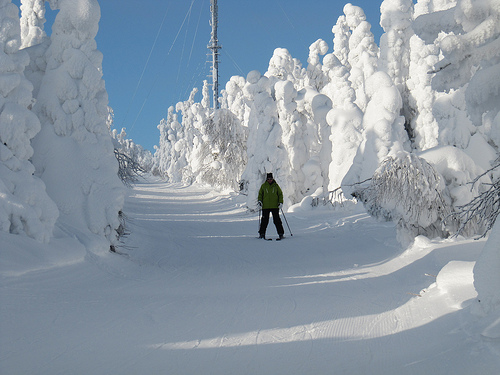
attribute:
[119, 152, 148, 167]
branch — dead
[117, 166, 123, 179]
branch — dead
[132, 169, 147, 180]
branch — dead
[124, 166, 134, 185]
branch — dead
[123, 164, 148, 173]
branch — dead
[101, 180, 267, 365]
slope — smooth, white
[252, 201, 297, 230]
poles — black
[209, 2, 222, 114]
pole — tall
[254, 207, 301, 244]
pants — black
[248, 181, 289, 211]
coat — green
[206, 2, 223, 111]
pole — power line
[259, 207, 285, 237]
pants — black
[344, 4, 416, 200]
tree — snow packed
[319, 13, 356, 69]
tree — snow packed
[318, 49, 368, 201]
tree — snow packed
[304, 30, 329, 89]
tree — snow packed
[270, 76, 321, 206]
tree — snow packed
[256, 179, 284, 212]
jacket — green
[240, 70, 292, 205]
tree — tall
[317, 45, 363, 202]
tree — tall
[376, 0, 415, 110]
tree — tall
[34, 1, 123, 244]
tree — tall, snowy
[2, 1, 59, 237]
tree — tall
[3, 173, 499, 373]
trail — snowy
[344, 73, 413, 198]
tree — snowy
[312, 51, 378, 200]
tree — snowy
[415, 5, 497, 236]
tree — snowy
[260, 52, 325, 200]
tree — snowy